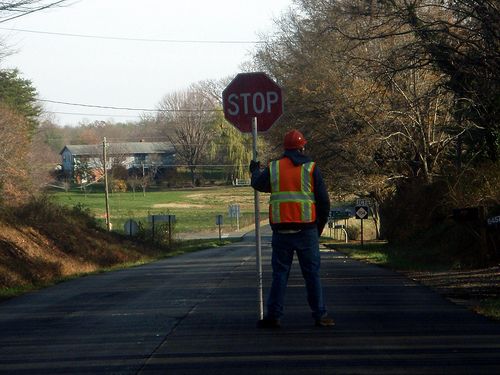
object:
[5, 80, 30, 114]
leaves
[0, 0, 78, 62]
tree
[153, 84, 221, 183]
tree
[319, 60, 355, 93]
leaves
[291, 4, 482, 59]
leaves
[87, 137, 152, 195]
tree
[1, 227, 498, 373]
gray road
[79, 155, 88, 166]
window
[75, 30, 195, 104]
white clouds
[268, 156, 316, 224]
vest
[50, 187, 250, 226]
grass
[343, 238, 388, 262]
grass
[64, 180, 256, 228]
field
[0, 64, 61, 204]
trees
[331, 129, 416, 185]
leaves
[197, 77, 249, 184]
tree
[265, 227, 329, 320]
jeans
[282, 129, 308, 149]
hat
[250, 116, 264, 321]
pole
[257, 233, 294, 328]
leg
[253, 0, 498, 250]
tree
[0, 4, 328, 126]
cloud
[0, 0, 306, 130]
sky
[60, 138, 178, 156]
roof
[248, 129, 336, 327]
man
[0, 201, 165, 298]
hill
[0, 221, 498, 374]
road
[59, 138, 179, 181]
building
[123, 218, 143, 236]
signs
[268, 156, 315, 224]
stripes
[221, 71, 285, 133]
sign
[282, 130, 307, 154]
head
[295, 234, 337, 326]
leg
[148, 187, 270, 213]
dirt